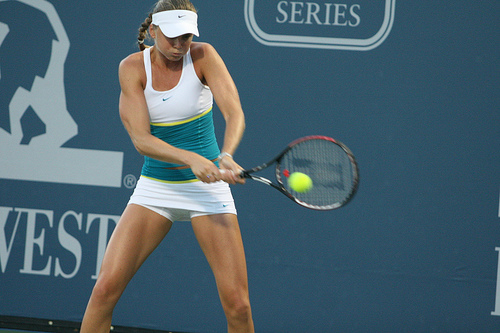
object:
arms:
[113, 55, 188, 173]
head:
[140, 0, 202, 62]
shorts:
[129, 197, 234, 225]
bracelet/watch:
[216, 150, 238, 159]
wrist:
[213, 148, 236, 161]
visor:
[152, 40, 191, 62]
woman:
[72, 0, 254, 332]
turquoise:
[136, 106, 224, 184]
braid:
[132, 13, 152, 50]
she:
[81, 0, 359, 331]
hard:
[195, 141, 267, 191]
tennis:
[89, 80, 245, 333]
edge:
[124, 197, 179, 211]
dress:
[125, 105, 238, 224]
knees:
[92, 276, 117, 296]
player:
[69, 0, 264, 332]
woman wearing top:
[124, 0, 226, 164]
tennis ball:
[285, 169, 319, 192]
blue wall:
[372, 74, 442, 104]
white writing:
[2, 201, 121, 279]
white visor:
[147, 8, 202, 39]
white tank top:
[140, 44, 221, 127]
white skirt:
[124, 170, 239, 219]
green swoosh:
[157, 94, 176, 103]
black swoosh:
[177, 14, 185, 20]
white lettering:
[269, 0, 366, 29]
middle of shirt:
[131, 105, 220, 187]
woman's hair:
[125, 1, 203, 52]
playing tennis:
[80, 0, 362, 333]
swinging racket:
[75, 1, 361, 331]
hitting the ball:
[198, 133, 363, 211]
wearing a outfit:
[73, 5, 361, 332]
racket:
[197, 135, 365, 210]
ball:
[279, 168, 317, 195]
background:
[2, 0, 500, 329]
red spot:
[278, 166, 289, 177]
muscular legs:
[187, 205, 259, 332]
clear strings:
[283, 147, 348, 199]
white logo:
[235, 1, 400, 52]